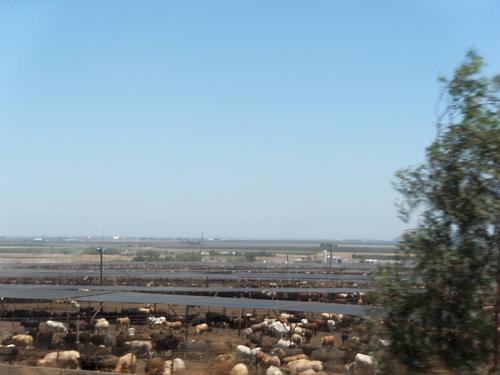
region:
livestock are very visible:
[70, 264, 248, 369]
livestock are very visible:
[102, 292, 338, 373]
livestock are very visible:
[118, 292, 228, 360]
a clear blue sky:
[0, 0, 499, 237]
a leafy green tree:
[355, 42, 498, 373]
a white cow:
[28, 345, 82, 372]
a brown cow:
[143, 352, 169, 374]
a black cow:
[147, 327, 183, 357]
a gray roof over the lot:
[2, 276, 398, 323]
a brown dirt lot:
[0, 257, 404, 373]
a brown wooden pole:
[92, 241, 109, 290]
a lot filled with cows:
[0, 295, 390, 373]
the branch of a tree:
[424, 87, 456, 141]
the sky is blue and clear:
[85, 80, 227, 200]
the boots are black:
[110, 35, 297, 192]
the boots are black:
[99, 25, 393, 225]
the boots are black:
[105, 131, 181, 208]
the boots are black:
[135, 142, 284, 260]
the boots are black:
[143, 147, 230, 288]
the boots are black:
[154, 182, 292, 366]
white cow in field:
[347, 347, 377, 368]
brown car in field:
[142, 349, 177, 369]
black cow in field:
[139, 325, 184, 365]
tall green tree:
[336, 167, 488, 333]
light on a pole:
[55, 243, 111, 320]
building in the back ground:
[284, 243, 354, 267]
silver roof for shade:
[80, 277, 311, 307]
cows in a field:
[140, 311, 315, 362]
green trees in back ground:
[92, 228, 284, 263]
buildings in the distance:
[27, 204, 221, 253]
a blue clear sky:
[1, 5, 383, 196]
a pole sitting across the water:
[90, 242, 107, 287]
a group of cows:
[21, 312, 331, 373]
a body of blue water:
[0, 283, 347, 306]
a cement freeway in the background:
[156, 230, 402, 250]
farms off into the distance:
[30, 233, 226, 241]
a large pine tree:
[382, 0, 497, 371]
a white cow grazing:
[236, 342, 265, 359]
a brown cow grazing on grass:
[81, 347, 130, 370]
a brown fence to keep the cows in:
[6, 288, 335, 327]